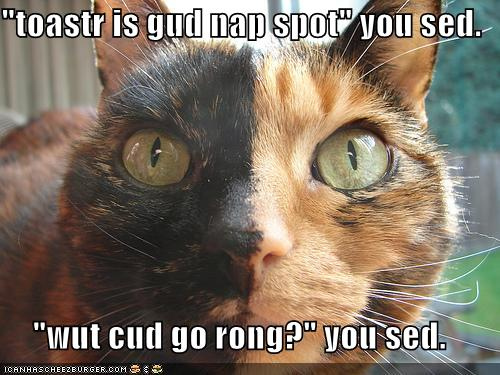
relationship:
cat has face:
[2, 1, 500, 374] [58, 34, 460, 367]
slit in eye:
[150, 136, 163, 168] [121, 126, 190, 186]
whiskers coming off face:
[14, 160, 499, 373] [58, 34, 460, 367]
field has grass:
[437, 248, 499, 342] [446, 248, 499, 343]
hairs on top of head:
[76, 1, 497, 99] [56, 0, 458, 373]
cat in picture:
[2, 1, 500, 374] [1, 1, 498, 372]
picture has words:
[1, 1, 498, 372] [14, 10, 475, 351]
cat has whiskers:
[2, 1, 500, 374] [14, 160, 499, 373]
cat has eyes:
[2, 1, 500, 374] [121, 124, 391, 191]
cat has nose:
[2, 1, 500, 374] [200, 221, 293, 288]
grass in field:
[446, 248, 499, 343] [437, 248, 499, 342]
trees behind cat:
[426, 0, 498, 151] [2, 1, 500, 374]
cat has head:
[2, 1, 500, 374] [56, 0, 458, 373]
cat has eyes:
[2, 1, 500, 374] [314, 126, 390, 190]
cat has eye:
[2, 1, 500, 374] [121, 127, 194, 187]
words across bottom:
[33, 321, 446, 355] [2, 302, 499, 373]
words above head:
[15, 10, 474, 39] [56, 0, 458, 373]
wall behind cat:
[0, 1, 102, 126] [2, 1, 500, 374]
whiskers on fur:
[14, 160, 499, 373] [56, 201, 462, 373]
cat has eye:
[2, 1, 500, 374] [121, 126, 190, 186]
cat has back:
[2, 1, 500, 374] [0, 104, 92, 361]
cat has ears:
[2, 1, 500, 374] [91, 1, 442, 123]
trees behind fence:
[426, 0, 498, 151] [444, 149, 499, 248]